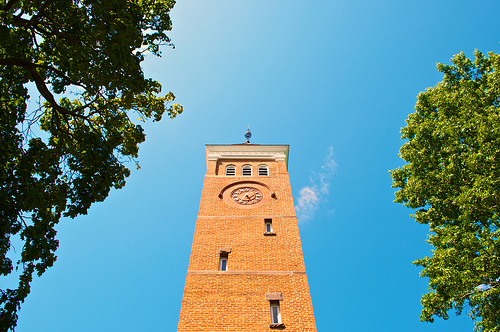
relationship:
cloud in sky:
[291, 146, 341, 224] [1, 2, 498, 329]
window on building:
[217, 257, 229, 271] [183, 130, 320, 330]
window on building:
[216, 245, 233, 274] [183, 130, 320, 330]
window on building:
[262, 290, 294, 327] [183, 130, 320, 330]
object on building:
[238, 124, 260, 147] [167, 129, 329, 329]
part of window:
[271, 311, 284, 326] [272, 300, 282, 325]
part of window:
[270, 313, 281, 329] [268, 294, 283, 329]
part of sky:
[327, 257, 356, 301] [1, 2, 498, 329]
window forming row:
[219, 160, 236, 175] [222, 161, 271, 176]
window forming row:
[257, 164, 270, 177] [222, 161, 271, 176]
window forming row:
[256, 157, 272, 175] [222, 161, 271, 176]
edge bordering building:
[283, 159, 315, 330] [175, 125, 320, 331]